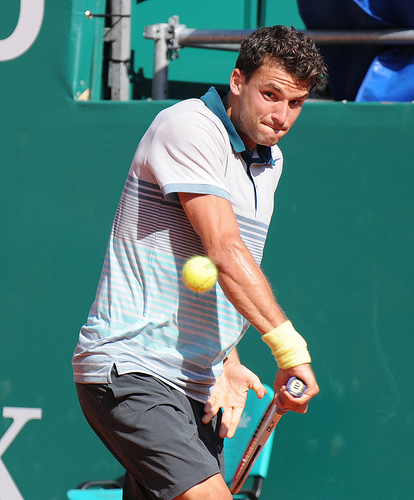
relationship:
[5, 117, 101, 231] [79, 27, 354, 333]
wall behind man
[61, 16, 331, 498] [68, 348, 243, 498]
man wears shorts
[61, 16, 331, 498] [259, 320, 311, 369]
man wears wristband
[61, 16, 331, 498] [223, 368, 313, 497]
man has racket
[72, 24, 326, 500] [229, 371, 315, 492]
man holding racket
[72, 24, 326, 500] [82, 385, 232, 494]
man wearing shorts